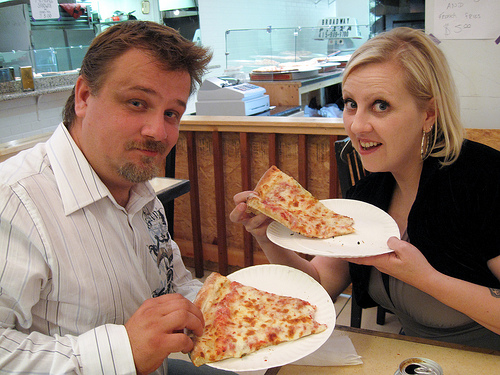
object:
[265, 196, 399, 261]
plate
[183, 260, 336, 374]
plate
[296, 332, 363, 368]
napkin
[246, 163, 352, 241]
pizza slice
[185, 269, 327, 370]
pizza slice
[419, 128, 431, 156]
earring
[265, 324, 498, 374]
table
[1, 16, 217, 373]
man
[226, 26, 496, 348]
woman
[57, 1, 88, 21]
pizza bag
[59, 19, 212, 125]
hair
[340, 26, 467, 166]
hair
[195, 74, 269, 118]
cash register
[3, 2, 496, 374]
room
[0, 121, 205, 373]
shirt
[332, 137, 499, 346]
shirt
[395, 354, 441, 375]
soda can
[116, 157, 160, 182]
goatee